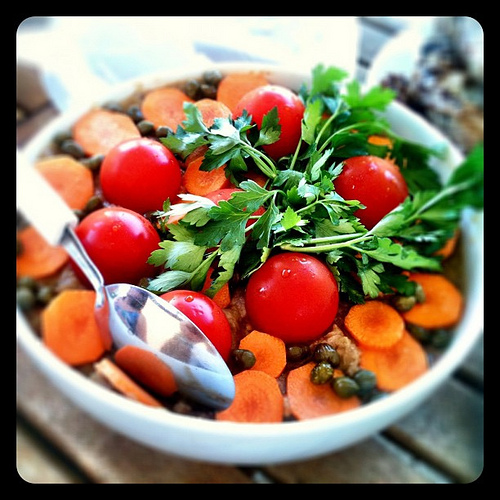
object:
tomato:
[333, 155, 409, 231]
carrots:
[72, 109, 141, 154]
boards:
[16, 338, 482, 482]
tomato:
[99, 135, 181, 217]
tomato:
[69, 205, 164, 290]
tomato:
[159, 289, 232, 362]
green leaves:
[147, 62, 484, 304]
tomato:
[235, 85, 307, 161]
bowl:
[16, 66, 484, 467]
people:
[112, 287, 148, 344]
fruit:
[244, 252, 339, 347]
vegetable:
[356, 329, 427, 391]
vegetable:
[379, 271, 462, 327]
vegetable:
[214, 370, 285, 422]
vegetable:
[141, 87, 196, 133]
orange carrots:
[344, 300, 403, 350]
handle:
[16, 163, 79, 248]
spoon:
[16, 152, 236, 410]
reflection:
[107, 285, 223, 371]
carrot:
[41, 288, 114, 366]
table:
[15, 92, 486, 483]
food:
[16, 71, 484, 423]